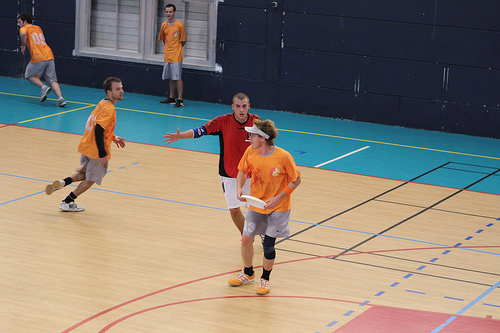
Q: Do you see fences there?
A: No, there are no fences.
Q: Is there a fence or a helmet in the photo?
A: No, there are no fences or helmets.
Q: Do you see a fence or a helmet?
A: No, there are no fences or helmets.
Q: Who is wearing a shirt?
A: The man is wearing a shirt.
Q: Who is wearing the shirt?
A: The man is wearing a shirt.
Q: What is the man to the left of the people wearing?
A: The man is wearing a shirt.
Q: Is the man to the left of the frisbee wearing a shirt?
A: Yes, the man is wearing a shirt.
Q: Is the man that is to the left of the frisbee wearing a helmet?
A: No, the man is wearing a shirt.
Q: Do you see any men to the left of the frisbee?
A: Yes, there is a man to the left of the frisbee.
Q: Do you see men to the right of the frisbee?
A: No, the man is to the left of the frisbee.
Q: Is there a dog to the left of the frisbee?
A: No, there is a man to the left of the frisbee.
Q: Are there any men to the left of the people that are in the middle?
A: Yes, there is a man to the left of the people.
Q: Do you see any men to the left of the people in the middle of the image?
A: Yes, there is a man to the left of the people.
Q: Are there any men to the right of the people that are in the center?
A: No, the man is to the left of the people.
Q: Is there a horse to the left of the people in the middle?
A: No, there is a man to the left of the people.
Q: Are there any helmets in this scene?
A: No, there are no helmets.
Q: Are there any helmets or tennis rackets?
A: No, there are no helmets or tennis rackets.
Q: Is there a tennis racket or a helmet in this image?
A: No, there are no helmets or rackets.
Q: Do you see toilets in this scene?
A: No, there are no toilets.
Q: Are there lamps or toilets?
A: No, there are no toilets or lamps.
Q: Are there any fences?
A: No, there are no fences.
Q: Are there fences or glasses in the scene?
A: No, there are no fences or glasses.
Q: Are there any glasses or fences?
A: No, there are no fences or glasses.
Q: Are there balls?
A: No, there are no balls.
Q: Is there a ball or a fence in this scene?
A: No, there are no balls or fences.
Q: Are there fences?
A: No, there are no fences.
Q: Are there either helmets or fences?
A: No, there are no fences or helmets.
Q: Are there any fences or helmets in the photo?
A: No, there are no fences or helmets.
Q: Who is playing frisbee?
A: The man is playing frisbee.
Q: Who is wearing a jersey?
A: The man is wearing a jersey.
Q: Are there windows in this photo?
A: Yes, there is a window.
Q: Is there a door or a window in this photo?
A: Yes, there is a window.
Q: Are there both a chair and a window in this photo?
A: No, there is a window but no chairs.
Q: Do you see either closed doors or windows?
A: Yes, there is a closed window.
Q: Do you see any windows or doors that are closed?
A: Yes, the window is closed.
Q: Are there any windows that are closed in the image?
A: Yes, there is a closed window.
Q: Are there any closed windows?
A: Yes, there is a closed window.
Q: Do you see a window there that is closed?
A: Yes, there is a window that is closed.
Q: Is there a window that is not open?
A: Yes, there is an closed window.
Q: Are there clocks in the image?
A: No, there are no clocks.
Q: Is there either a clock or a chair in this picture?
A: No, there are no clocks or chairs.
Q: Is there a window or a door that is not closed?
A: No, there is a window but it is closed.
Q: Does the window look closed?
A: Yes, the window is closed.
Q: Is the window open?
A: No, the window is closed.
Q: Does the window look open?
A: No, the window is closed.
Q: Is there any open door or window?
A: No, there is a window but it is closed.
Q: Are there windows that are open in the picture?
A: No, there is a window but it is closed.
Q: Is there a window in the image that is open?
A: No, there is a window but it is closed.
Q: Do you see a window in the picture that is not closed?
A: No, there is a window but it is closed.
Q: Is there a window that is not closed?
A: No, there is a window but it is closed.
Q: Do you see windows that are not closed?
A: No, there is a window but it is closed.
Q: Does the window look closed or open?
A: The window is closed.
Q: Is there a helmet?
A: No, there are no helmets.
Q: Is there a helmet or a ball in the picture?
A: No, there are no helmets or balls.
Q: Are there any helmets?
A: No, there are no helmets.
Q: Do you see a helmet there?
A: No, there are no helmets.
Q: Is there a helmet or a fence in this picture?
A: No, there are no helmets or fences.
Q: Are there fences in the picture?
A: No, there are no fences.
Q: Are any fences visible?
A: No, there are no fences.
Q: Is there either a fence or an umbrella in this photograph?
A: No, there are no fences or umbrellas.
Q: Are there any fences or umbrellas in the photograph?
A: No, there are no fences or umbrellas.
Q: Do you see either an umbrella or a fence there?
A: No, there are no fences or umbrellas.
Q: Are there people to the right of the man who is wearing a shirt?
A: Yes, there are people to the right of the man.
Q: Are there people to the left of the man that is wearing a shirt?
A: No, the people are to the right of the man.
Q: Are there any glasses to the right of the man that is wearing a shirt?
A: No, there are people to the right of the man.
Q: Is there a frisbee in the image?
A: Yes, there is a frisbee.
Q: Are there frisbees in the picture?
A: Yes, there is a frisbee.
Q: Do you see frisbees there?
A: Yes, there is a frisbee.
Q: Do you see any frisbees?
A: Yes, there is a frisbee.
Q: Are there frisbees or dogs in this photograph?
A: Yes, there is a frisbee.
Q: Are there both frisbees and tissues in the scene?
A: No, there is a frisbee but no tissues.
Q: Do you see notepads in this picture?
A: No, there are no notepads.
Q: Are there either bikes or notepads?
A: No, there are no notepads or bikes.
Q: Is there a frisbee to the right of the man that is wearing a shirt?
A: Yes, there is a frisbee to the right of the man.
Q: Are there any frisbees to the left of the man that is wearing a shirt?
A: No, the frisbee is to the right of the man.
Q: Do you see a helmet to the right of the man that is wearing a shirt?
A: No, there is a frisbee to the right of the man.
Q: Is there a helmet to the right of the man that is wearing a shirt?
A: No, there is a frisbee to the right of the man.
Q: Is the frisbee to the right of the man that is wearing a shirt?
A: Yes, the frisbee is to the right of the man.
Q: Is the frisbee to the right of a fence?
A: No, the frisbee is to the right of the man.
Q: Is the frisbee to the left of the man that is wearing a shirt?
A: No, the frisbee is to the right of the man.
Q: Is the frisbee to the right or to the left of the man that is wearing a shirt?
A: The frisbee is to the right of the man.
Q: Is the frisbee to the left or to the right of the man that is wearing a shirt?
A: The frisbee is to the right of the man.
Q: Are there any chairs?
A: No, there are no chairs.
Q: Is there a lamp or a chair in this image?
A: No, there are no chairs or lamps.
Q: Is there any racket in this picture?
A: No, there are no rackets.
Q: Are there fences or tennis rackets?
A: No, there are no tennis rackets or fences.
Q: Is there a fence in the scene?
A: No, there are no fences.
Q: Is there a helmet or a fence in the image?
A: No, there are no fences or helmets.